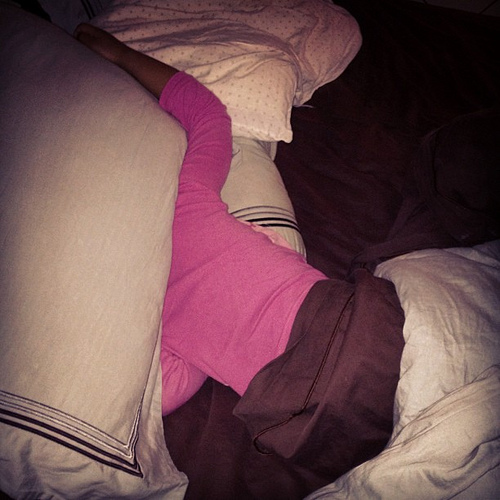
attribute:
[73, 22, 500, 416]
person — sleeping, wearing pink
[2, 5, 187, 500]
pillow — over the person head, over person's head, white, large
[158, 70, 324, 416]
shirt — pink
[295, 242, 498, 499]
coverlet — white, folded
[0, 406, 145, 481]
trim — black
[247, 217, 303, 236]
trim — black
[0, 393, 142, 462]
trim — white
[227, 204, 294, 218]
trim — white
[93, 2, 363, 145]
material — light pink, white, dotted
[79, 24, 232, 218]
arm — sticking out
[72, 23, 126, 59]
hand — closed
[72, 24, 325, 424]
girl — sleeping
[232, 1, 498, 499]
blanket — brown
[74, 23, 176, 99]
skin — exposed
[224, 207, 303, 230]
embellishment — black, silver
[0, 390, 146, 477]
embellishment — black, silver